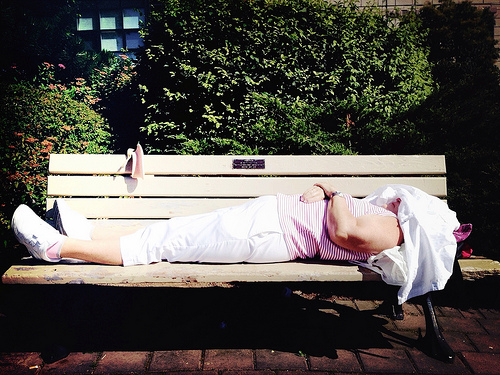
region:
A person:
[101, 187, 498, 354]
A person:
[149, 143, 372, 280]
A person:
[248, 191, 363, 314]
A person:
[201, 179, 394, 357]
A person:
[346, 229, 405, 338]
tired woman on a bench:
[43, 175, 477, 280]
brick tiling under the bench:
[85, 308, 454, 371]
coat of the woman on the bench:
[387, 179, 473, 311]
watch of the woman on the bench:
[323, 191, 363, 205]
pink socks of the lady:
[45, 241, 70, 270]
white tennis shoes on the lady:
[14, 204, 68, 282]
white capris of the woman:
[113, 229, 294, 270]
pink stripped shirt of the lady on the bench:
[282, 188, 407, 257]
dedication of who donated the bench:
[210, 154, 294, 175]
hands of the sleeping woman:
[299, 183, 345, 211]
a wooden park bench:
[5, 148, 463, 365]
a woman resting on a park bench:
[8, 180, 417, 265]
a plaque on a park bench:
[228, 158, 275, 173]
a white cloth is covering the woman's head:
[365, 187, 458, 304]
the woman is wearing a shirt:
[273, 186, 401, 264]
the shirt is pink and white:
[278, 185, 397, 263]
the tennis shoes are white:
[8, 194, 98, 271]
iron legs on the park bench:
[376, 275, 458, 367]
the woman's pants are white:
[112, 194, 290, 279]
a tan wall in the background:
[322, 0, 499, 75]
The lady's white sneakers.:
[7, 201, 97, 261]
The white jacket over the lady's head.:
[364, 180, 461, 297]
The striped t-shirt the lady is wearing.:
[289, 183, 414, 262]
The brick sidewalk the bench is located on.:
[15, 295, 497, 372]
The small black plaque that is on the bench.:
[227, 155, 269, 172]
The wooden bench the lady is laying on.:
[10, 141, 498, 289]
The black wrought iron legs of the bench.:
[20, 290, 464, 374]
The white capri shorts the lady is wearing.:
[112, 199, 279, 269]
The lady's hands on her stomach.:
[302, 176, 349, 212]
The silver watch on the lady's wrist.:
[326, 187, 346, 204]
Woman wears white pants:
[111, 192, 289, 271]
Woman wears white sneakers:
[8, 183, 82, 288]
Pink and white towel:
[112, 133, 157, 196]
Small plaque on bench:
[189, 150, 311, 181]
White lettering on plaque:
[236, 160, 265, 168]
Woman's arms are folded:
[298, 175, 360, 244]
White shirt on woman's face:
[359, 168, 459, 308]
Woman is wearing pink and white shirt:
[281, 203, 323, 259]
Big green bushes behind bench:
[125, 58, 429, 134]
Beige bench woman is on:
[287, 153, 461, 185]